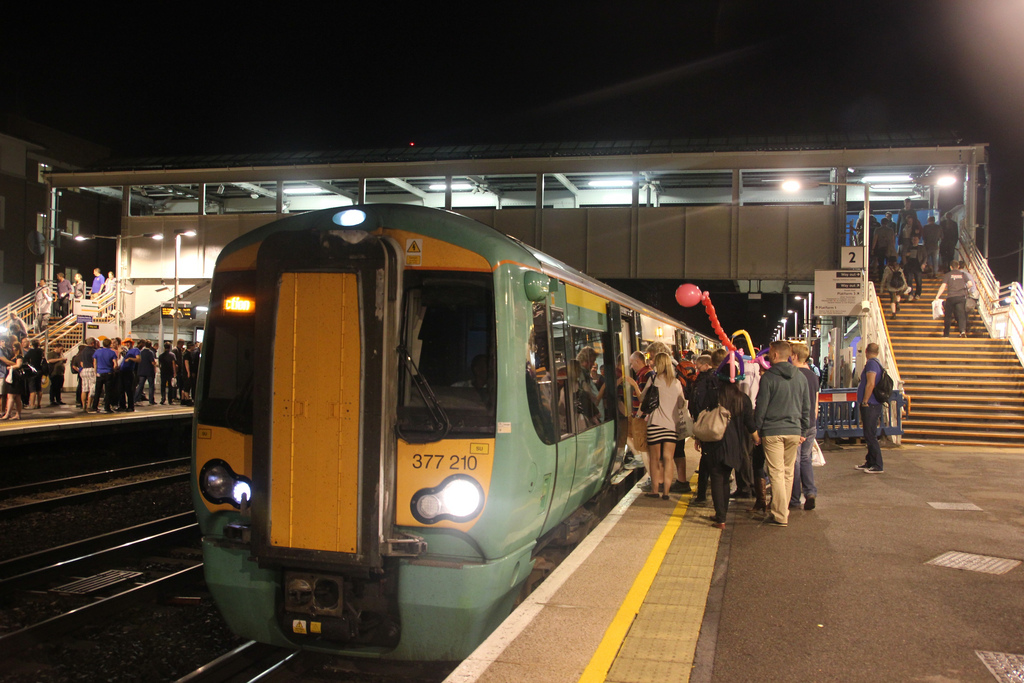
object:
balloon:
[674, 284, 737, 352]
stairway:
[844, 261, 1024, 443]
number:
[412, 454, 477, 470]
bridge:
[54, 160, 976, 275]